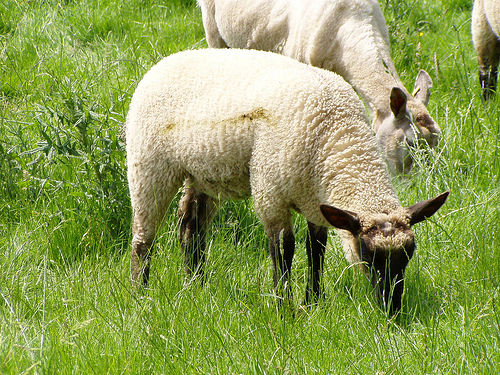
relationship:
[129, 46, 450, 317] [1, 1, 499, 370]
sheep eating grass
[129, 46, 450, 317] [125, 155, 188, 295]
sheep has leg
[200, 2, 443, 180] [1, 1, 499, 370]
sheep eating grass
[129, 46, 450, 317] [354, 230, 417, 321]
sheep has face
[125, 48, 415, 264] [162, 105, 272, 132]
wool has stain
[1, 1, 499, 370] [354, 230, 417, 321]
grass covering face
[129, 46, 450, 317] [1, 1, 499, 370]
sheep standing over grass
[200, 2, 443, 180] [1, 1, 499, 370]
sheep standing over grass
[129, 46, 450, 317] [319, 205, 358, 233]
sheep has ear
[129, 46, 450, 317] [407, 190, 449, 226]
sheep has ear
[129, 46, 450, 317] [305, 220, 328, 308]
sheep has leg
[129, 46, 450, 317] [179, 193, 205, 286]
sheep has leg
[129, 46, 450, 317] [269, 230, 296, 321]
sheep has leg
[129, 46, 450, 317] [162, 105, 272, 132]
sheep has stain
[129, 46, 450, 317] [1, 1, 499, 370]
sheep standing on grass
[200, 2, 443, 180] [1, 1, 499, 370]
sheep standing on grass